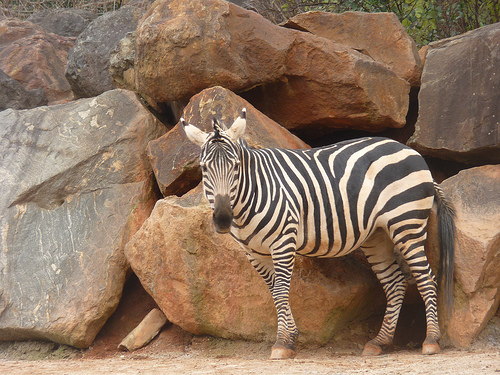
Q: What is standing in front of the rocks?
A: Zebra.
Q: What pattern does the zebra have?
A: Striped.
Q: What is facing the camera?
A: A zebra.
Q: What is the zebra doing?
A: Standing.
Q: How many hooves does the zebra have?
A: Four.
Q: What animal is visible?
A: A zebra.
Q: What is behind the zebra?
A: Rocks.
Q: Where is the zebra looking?
A: The camera.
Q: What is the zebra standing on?
A: Dirt.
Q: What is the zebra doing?
A: Standing.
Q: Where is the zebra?
A: Outside by a stone wall.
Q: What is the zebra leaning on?
A: Boulder.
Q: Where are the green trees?
A: In the background behind the boulders.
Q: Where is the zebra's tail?
A: Resting on the boulder.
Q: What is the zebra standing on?
A: Sandy dirt.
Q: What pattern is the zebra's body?
A: Stripes.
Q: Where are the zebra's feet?
A: On the ground.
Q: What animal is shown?
A: A zebra.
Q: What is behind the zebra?
A: Rocks.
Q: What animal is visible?
A: Zebra.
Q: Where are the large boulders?
A: Behind the zebra.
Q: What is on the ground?
A: Dirt.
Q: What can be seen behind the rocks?
A: Trees and vegetation.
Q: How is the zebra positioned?
A: Standing.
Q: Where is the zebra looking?
A: Toward the camera.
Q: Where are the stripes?
A: On the zebra.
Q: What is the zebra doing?
A: Standing and looking at the camera.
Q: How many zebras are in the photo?
A: One.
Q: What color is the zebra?
A: White and black.